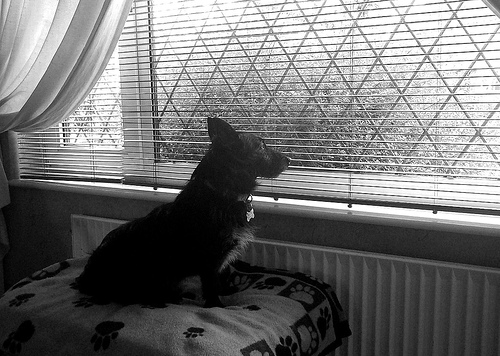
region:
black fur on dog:
[167, 258, 177, 266]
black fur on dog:
[211, 281, 218, 290]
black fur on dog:
[114, 287, 121, 289]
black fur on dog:
[230, 177, 235, 179]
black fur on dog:
[274, 150, 276, 160]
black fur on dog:
[94, 267, 105, 272]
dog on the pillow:
[85, 112, 304, 310]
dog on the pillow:
[57, 115, 300, 291]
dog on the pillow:
[52, 99, 291, 321]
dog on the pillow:
[88, 125, 295, 325]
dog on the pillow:
[61, 115, 306, 323]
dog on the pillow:
[42, 99, 299, 326]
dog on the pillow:
[80, 113, 313, 335]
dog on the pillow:
[47, 105, 309, 327]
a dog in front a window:
[63, 47, 332, 314]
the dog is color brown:
[59, 114, 299, 320]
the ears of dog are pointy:
[193, 103, 250, 158]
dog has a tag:
[238, 185, 262, 231]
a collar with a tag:
[186, 163, 263, 223]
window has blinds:
[0, 0, 499, 221]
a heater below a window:
[69, 114, 497, 354]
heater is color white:
[58, 208, 498, 355]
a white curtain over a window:
[1, 4, 151, 191]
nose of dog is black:
[283, 150, 295, 167]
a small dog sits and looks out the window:
[66, 108, 294, 312]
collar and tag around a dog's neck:
[186, 166, 259, 223]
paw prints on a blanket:
[3, 245, 353, 355]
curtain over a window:
[1, 2, 135, 264]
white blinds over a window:
[13, 0, 499, 215]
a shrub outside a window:
[141, 2, 498, 187]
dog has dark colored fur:
[72, 112, 295, 317]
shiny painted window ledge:
[6, 174, 499, 238]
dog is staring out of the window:
[68, 108, 296, 317]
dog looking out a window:
[27, 89, 406, 331]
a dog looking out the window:
[22, 54, 417, 319]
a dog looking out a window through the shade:
[11, 33, 468, 331]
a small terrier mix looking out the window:
[48, 106, 433, 331]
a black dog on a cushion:
[37, 110, 319, 352]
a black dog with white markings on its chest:
[45, 97, 337, 352]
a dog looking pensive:
[51, 80, 356, 351]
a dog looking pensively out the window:
[45, 111, 355, 326]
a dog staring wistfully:
[15, 90, 495, 351]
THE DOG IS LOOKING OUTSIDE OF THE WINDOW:
[185, 222, 358, 259]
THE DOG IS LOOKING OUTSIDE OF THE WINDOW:
[212, 252, 357, 301]